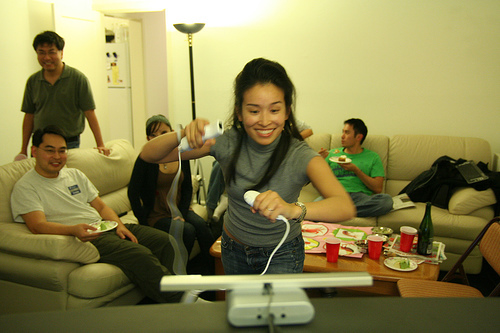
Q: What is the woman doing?
A: Playing wii.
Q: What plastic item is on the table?
A: Red cups.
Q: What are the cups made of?
A: Plastic.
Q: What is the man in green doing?
A: Eating.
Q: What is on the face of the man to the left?
A: Glasses.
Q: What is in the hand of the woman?
A: A wii.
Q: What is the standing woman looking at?
A: Television.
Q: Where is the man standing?
A: Behind sofa.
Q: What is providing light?
A: Floor lamp.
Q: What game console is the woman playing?
A: Wii.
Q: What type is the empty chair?
A: Folding chair.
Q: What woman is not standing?
A: Woman sitting on sofa.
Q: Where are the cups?
A: On coffee table.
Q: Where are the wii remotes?
A: In woman's hands.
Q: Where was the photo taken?
A: In livingroom.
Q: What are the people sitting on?
A: Couches.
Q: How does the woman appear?
A: Happy.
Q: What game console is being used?
A: Wii.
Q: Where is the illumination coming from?
A: Corner lamp.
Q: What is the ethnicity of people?
A: Asian.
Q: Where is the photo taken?
A: Living room.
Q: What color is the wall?
A: White.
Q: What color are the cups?
A: Red.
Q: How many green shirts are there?
A: One.